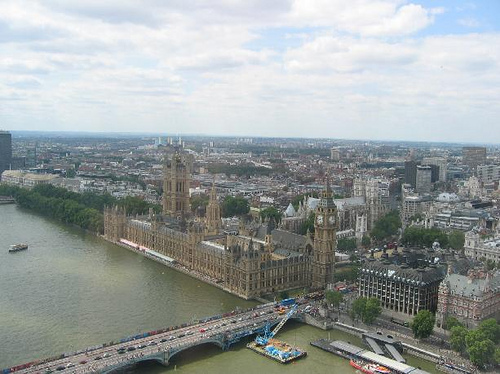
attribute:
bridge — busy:
[64, 319, 316, 366]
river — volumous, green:
[7, 240, 234, 338]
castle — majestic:
[123, 155, 345, 302]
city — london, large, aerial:
[68, 114, 497, 324]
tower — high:
[164, 140, 205, 218]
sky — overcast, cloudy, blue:
[6, 3, 498, 143]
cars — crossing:
[200, 313, 277, 326]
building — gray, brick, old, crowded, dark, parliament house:
[275, 181, 372, 297]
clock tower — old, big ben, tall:
[305, 177, 337, 293]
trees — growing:
[442, 317, 499, 362]